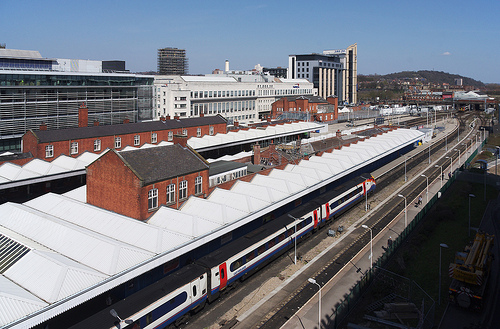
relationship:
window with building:
[67, 135, 85, 155] [21, 115, 233, 160]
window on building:
[93, 138, 100, 151] [18, 105, 229, 161]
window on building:
[148, 185, 158, 207] [285, 52, 343, 100]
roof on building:
[110, 142, 210, 185] [83, 134, 211, 229]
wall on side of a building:
[84, 153, 141, 220] [83, 134, 211, 229]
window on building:
[67, 131, 99, 176] [9, 46, 344, 288]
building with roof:
[20, 114, 230, 165] [21, 112, 227, 144]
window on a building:
[193, 174, 203, 192] [78, 134, 208, 219]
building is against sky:
[158, 46, 185, 71] [221, 9, 313, 44]